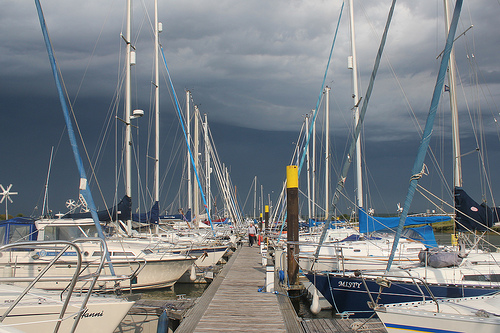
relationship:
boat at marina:
[0, 234, 137, 331] [21, 35, 481, 311]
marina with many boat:
[21, 35, 481, 311] [0, 234, 137, 331]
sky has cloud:
[2, 1, 497, 224] [4, 1, 484, 77]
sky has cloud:
[2, 1, 497, 224] [8, 45, 498, 150]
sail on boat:
[383, 0, 461, 273] [306, 0, 498, 310]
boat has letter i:
[303, 252, 500, 318] [344, 279, 349, 289]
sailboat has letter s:
[364, 292, 498, 333] [337, 279, 343, 289]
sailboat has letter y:
[297, 260, 499, 312] [355, 282, 365, 289]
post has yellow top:
[286, 163, 300, 285] [285, 164, 297, 189]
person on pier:
[244, 219, 260, 243] [173, 228, 381, 330]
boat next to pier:
[364, 289, 496, 330] [172, 230, 305, 327]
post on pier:
[258, 239, 265, 256] [171, 216, 309, 331]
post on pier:
[258, 245, 269, 267] [171, 216, 309, 331]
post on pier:
[265, 264, 275, 292] [171, 216, 309, 331]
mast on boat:
[114, 0, 140, 230] [113, 217, 232, 262]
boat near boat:
[0, 219, 195, 296] [2, 283, 133, 331]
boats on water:
[0, 3, 253, 330] [413, 230, 498, 248]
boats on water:
[261, 0, 498, 332] [76, 275, 208, 305]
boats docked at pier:
[261, 0, 498, 332] [129, 203, 381, 331]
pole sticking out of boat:
[336, 0, 377, 231] [274, 230, 499, 267]